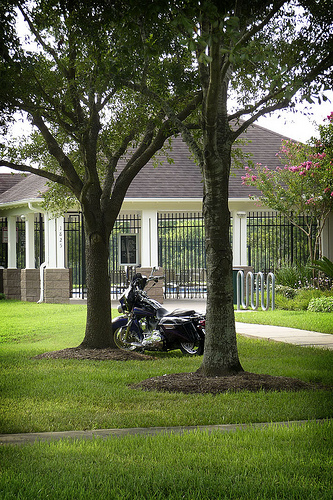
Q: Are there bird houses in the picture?
A: No, there are no bird houses.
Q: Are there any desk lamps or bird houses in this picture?
A: No, there are no bird houses or desk lamps.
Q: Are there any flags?
A: No, there are no flags.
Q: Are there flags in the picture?
A: No, there are no flags.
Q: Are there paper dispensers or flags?
A: No, there are no flags or paper dispensers.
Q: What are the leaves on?
A: The leaves are on the trees.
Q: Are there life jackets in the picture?
A: No, there are no life jackets.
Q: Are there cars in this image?
A: No, there are no cars.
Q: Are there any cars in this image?
A: No, there are no cars.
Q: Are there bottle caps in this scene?
A: No, there are no bottle caps.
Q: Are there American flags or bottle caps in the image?
A: No, there are no bottle caps or American flags.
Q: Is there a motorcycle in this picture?
A: Yes, there is a motorcycle.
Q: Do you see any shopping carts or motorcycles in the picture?
A: Yes, there is a motorcycle.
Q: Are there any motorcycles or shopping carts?
A: Yes, there is a motorcycle.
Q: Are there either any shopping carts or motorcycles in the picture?
A: Yes, there is a motorcycle.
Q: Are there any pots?
A: No, there are no pots.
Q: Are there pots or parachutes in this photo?
A: No, there are no pots or parachutes.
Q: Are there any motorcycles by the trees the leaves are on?
A: Yes, there is a motorcycle by the trees.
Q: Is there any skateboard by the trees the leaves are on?
A: No, there is a motorcycle by the trees.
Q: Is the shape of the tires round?
A: Yes, the tires are round.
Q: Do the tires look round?
A: Yes, the tires are round.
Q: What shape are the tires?
A: The tires are round.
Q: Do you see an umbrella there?
A: No, there are no umbrellas.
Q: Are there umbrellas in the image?
A: No, there are no umbrellas.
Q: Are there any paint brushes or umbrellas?
A: No, there are no umbrellas or paint brushes.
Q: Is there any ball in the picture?
A: No, there are no balls.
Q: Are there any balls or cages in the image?
A: No, there are no balls or cages.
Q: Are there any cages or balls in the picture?
A: No, there are no balls or cages.